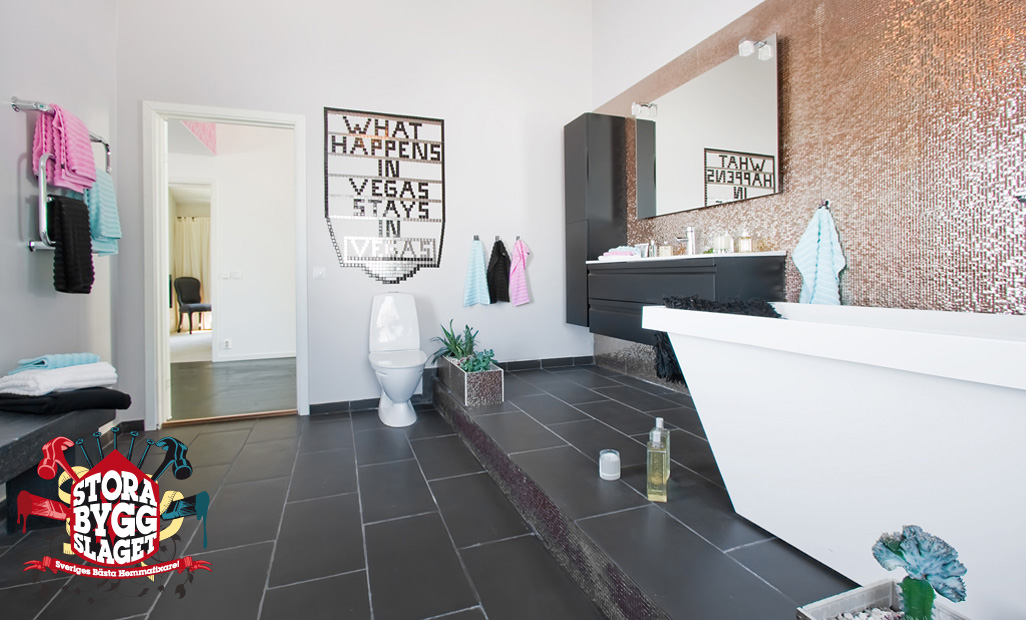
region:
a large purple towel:
[10, 97, 97, 195]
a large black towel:
[35, 184, 98, 301]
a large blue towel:
[61, 163, 122, 255]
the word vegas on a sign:
[340, 170, 433, 202]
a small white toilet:
[360, 283, 431, 436]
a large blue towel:
[788, 201, 851, 312]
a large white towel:
[4, 357, 118, 395]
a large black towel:
[1, 382, 134, 417]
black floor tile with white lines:
[1, 355, 924, 617]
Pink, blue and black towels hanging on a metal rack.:
[8, 91, 123, 297]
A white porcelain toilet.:
[363, 287, 430, 429]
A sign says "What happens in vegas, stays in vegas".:
[320, 104, 450, 287]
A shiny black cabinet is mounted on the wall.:
[561, 111, 629, 323]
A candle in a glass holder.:
[595, 447, 622, 482]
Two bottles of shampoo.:
[640, 412, 675, 502]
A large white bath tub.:
[639, 296, 1024, 618]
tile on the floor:
[750, 550, 786, 571]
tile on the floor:
[705, 510, 748, 536]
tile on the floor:
[640, 529, 700, 587]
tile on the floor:
[540, 471, 586, 498]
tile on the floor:
[501, 419, 564, 446]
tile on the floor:
[518, 586, 550, 602]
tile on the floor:
[439, 434, 482, 467]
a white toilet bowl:
[365, 283, 429, 432]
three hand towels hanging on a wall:
[463, 224, 540, 311]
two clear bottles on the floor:
[642, 406, 671, 505]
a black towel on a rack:
[42, 190, 97, 298]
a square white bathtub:
[646, 287, 1022, 602]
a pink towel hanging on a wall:
[510, 233, 537, 309]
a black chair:
[174, 262, 204, 335]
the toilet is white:
[370, 290, 424, 427]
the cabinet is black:
[562, 111, 627, 324]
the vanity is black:
[587, 252, 784, 348]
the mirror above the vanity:
[583, 31, 788, 349]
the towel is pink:
[30, 103, 95, 190]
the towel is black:
[45, 192, 94, 291]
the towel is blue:
[65, 164, 119, 256]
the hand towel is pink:
[505, 236, 532, 303]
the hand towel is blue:
[488, 240, 511, 301]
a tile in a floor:
[173, 422, 252, 471]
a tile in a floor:
[241, 410, 298, 442]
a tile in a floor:
[214, 439, 297, 481]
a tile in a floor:
[156, 539, 280, 618]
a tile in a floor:
[293, 414, 356, 450]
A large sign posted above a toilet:
[321, 104, 448, 288]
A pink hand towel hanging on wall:
[506, 238, 533, 308]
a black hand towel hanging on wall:
[487, 238, 511, 301]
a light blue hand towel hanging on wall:
[462, 240, 489, 303]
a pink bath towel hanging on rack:
[31, 100, 96, 193]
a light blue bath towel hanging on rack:
[81, 167, 124, 254]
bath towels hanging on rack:
[6, 98, 121, 288]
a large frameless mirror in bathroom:
[633, 35, 781, 219]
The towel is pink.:
[38, 110, 101, 190]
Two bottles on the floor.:
[623, 421, 700, 510]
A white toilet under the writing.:
[356, 280, 430, 454]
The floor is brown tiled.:
[217, 434, 605, 604]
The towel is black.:
[43, 188, 98, 287]